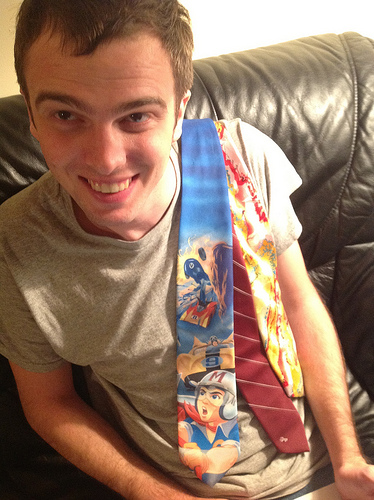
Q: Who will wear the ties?
A: The sitting man.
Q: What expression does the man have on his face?
A: Smile.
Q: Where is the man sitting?
A: On a couch.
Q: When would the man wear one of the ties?
A: A dressy occasion.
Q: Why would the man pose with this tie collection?
A: He's proud.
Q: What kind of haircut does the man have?
A: Short.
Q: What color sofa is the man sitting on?
A: Brown.